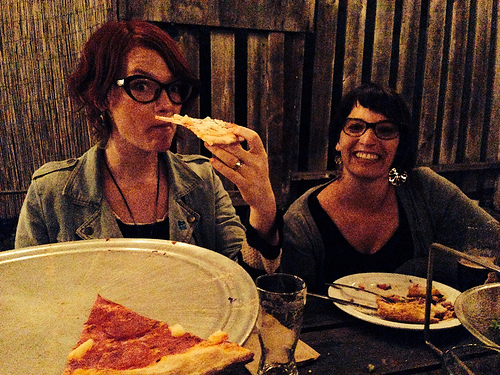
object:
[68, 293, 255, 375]
pizza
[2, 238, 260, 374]
pan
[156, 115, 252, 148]
pizza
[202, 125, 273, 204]
hand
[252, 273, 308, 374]
glass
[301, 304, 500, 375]
table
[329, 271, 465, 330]
plate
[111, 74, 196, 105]
glasses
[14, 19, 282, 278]
woman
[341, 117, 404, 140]
glasses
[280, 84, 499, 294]
woman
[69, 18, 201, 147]
hair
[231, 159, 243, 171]
ring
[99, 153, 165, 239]
nacklace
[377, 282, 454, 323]
food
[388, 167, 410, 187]
earring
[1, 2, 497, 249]
wall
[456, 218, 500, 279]
glass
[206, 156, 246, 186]
finger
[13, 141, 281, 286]
jacket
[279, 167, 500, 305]
sweater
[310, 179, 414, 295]
shirt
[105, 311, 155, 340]
pepperoni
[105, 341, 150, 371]
pepperoni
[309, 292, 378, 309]
utensil